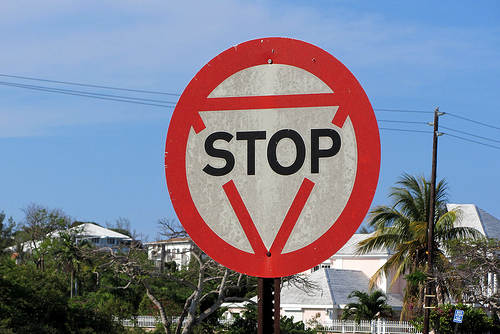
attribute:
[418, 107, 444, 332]
pole — wooden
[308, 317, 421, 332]
fence — white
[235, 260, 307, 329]
metal post — brown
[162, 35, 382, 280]
stop — circular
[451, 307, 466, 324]
sign — blue, white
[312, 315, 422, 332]
fence — white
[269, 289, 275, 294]
dot — circular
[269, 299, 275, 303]
dot — circular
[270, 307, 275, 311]
dot — circular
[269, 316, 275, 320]
dot — circular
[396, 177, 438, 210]
leaf — green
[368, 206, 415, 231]
leaf — green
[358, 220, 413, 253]
leaf — green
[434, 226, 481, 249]
leaf — green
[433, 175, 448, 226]
leaf — green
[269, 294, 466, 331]
fence — white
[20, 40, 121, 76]
sky — blue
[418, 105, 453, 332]
telephon pole — brown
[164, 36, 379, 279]
sign — round, white, black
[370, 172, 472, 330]
palm trees — tall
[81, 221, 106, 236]
roof — white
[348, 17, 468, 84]
sky — white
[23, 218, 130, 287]
house — light blue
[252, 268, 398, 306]
shingle rooftop — white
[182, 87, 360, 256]
triangle — broken